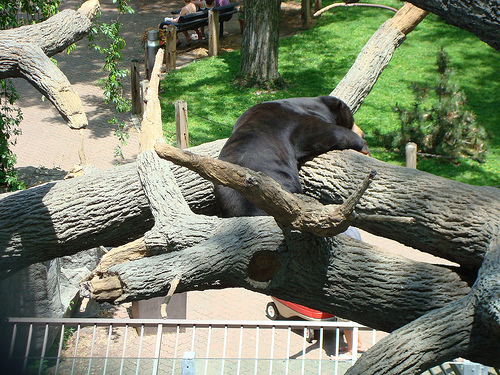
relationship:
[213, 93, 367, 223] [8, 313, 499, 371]
animal inside fence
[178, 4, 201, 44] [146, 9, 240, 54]
person sitting on bench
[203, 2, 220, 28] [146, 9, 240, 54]
person sitting on bench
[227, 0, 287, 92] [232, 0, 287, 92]
tree has tree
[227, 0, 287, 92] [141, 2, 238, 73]
tree near bench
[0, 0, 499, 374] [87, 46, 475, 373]
tree has limb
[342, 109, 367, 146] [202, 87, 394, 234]
nose of bear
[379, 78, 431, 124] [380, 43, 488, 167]
leaves of bush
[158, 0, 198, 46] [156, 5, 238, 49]
person sitting on bench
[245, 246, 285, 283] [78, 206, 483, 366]
hole in tree trunk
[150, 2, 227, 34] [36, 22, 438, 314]
bench at zoo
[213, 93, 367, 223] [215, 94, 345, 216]
animal has fur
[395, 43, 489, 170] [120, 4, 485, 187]
bush on ground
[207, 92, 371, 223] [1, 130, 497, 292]
animal on branch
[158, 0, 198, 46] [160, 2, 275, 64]
person sitting on bench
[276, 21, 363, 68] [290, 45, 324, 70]
patch of grass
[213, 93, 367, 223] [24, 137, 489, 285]
animal sleeping on tree